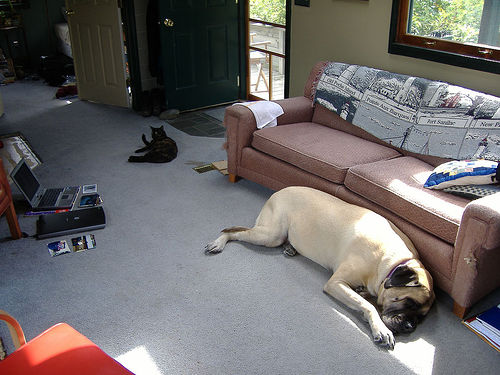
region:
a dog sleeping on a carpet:
[202, 172, 438, 344]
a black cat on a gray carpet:
[121, 120, 182, 175]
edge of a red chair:
[3, 300, 163, 370]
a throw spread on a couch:
[307, 63, 499, 149]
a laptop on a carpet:
[12, 165, 80, 209]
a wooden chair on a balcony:
[246, 33, 276, 93]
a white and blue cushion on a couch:
[418, 145, 498, 202]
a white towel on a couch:
[231, 89, 292, 134]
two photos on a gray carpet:
[39, 232, 104, 259]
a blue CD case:
[76, 190, 108, 210]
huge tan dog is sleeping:
[194, 162, 449, 364]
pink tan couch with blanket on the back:
[213, 56, 498, 268]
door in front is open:
[157, 5, 249, 107]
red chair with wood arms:
[5, 305, 105, 372]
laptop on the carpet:
[13, 160, 83, 230]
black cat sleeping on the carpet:
[128, 98, 174, 183]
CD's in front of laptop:
[47, 186, 122, 256]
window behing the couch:
[395, 0, 496, 86]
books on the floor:
[465, 306, 498, 339]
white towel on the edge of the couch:
[223, 95, 288, 147]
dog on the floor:
[198, 178, 447, 355]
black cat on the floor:
[123, 120, 185, 172]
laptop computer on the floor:
[7, 156, 83, 217]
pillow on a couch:
[419, 146, 499, 193]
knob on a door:
[157, 11, 178, 32]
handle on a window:
[418, 35, 440, 52]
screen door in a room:
[241, 0, 300, 114]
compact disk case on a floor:
[42, 237, 74, 261]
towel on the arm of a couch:
[228, 96, 294, 136]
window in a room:
[380, 1, 499, 79]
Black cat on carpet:
[121, 113, 182, 175]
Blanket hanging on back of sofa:
[311, 49, 498, 165]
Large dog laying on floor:
[202, 176, 437, 349]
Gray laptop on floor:
[6, 152, 81, 214]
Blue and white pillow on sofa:
[414, 149, 499, 209]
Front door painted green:
[152, 5, 257, 114]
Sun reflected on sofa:
[385, 151, 467, 229]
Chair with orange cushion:
[1, 291, 146, 373]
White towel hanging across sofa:
[228, 98, 291, 138]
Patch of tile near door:
[161, 95, 228, 147]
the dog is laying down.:
[198, 170, 440, 354]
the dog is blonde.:
[197, 173, 437, 354]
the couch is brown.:
[215, 42, 498, 322]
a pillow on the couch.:
[417, 140, 498, 199]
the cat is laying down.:
[121, 115, 181, 164]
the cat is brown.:
[124, 117, 180, 170]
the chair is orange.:
[1, 305, 151, 374]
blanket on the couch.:
[308, 51, 498, 173]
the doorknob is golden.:
[157, 15, 178, 30]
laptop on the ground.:
[10, 150, 87, 217]